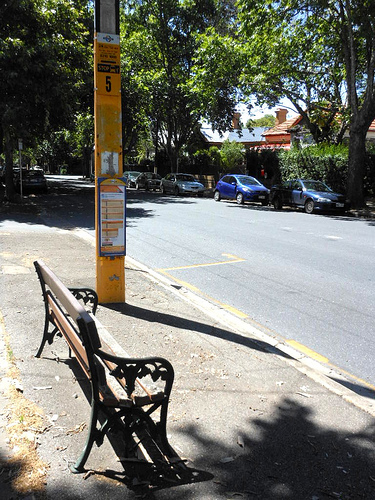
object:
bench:
[31, 256, 187, 478]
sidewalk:
[2, 197, 375, 500]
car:
[272, 175, 348, 217]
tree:
[240, 0, 374, 207]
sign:
[93, 32, 121, 100]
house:
[260, 107, 374, 152]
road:
[37, 173, 374, 395]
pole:
[93, 3, 128, 308]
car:
[210, 170, 270, 207]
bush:
[262, 145, 373, 193]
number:
[101, 72, 115, 95]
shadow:
[96, 302, 374, 402]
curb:
[125, 255, 373, 421]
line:
[154, 255, 248, 273]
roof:
[261, 107, 317, 138]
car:
[14, 165, 50, 195]